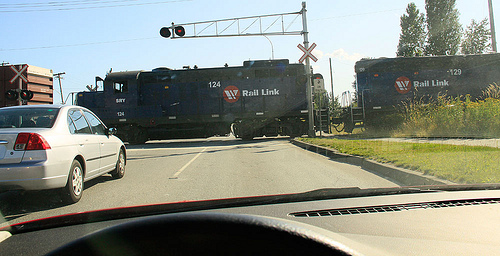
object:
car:
[0, 104, 129, 204]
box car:
[0, 62, 55, 106]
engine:
[74, 59, 332, 145]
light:
[174, 25, 185, 36]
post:
[299, 0, 317, 138]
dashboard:
[0, 184, 500, 254]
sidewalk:
[317, 133, 500, 150]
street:
[1, 136, 415, 228]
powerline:
[0, 1, 194, 14]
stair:
[312, 105, 331, 132]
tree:
[395, 1, 428, 56]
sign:
[296, 43, 320, 62]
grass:
[296, 135, 500, 193]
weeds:
[397, 84, 500, 137]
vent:
[289, 195, 499, 220]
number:
[207, 79, 222, 88]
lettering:
[243, 87, 281, 98]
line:
[170, 147, 212, 180]